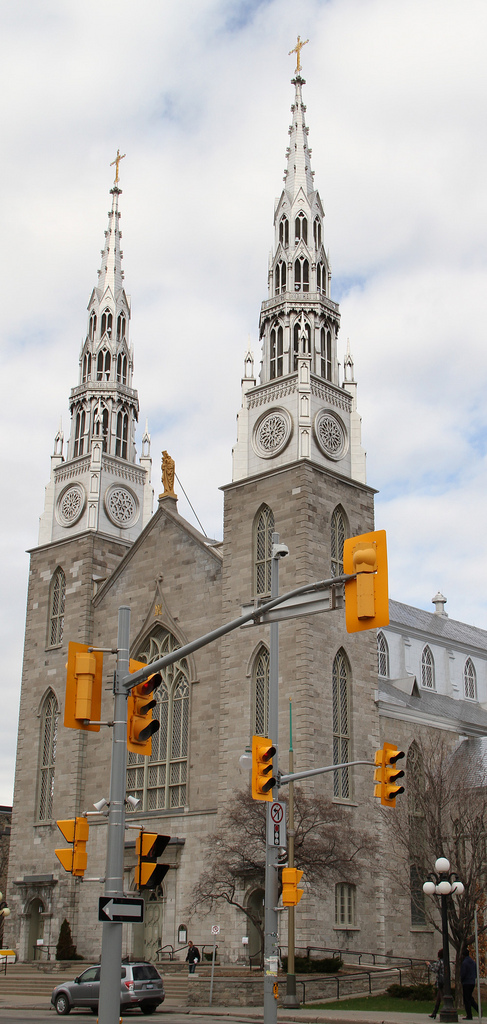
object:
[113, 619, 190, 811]
window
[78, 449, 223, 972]
building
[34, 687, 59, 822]
window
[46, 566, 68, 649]
window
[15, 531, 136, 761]
building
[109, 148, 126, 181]
cross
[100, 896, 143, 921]
arrow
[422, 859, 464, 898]
lamps